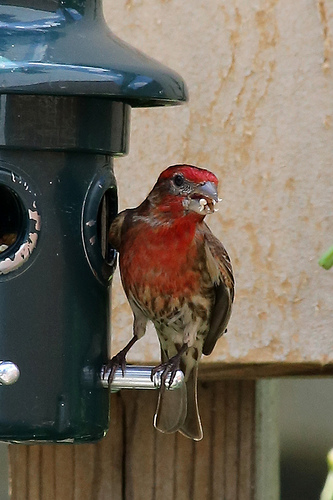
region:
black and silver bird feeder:
[0, 1, 186, 443]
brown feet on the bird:
[101, 336, 190, 389]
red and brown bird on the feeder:
[97, 161, 236, 441]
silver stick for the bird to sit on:
[99, 360, 184, 392]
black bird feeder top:
[0, 0, 191, 108]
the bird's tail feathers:
[152, 333, 205, 443]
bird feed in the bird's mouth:
[198, 195, 222, 216]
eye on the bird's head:
[170, 171, 186, 189]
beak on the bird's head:
[182, 180, 220, 216]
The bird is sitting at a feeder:
[29, 122, 321, 482]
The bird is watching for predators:
[52, 156, 276, 487]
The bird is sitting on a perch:
[54, 162, 327, 469]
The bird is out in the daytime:
[53, 162, 311, 481]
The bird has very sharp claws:
[52, 155, 310, 488]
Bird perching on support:
[111, 162, 240, 379]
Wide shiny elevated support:
[116, 368, 151, 390]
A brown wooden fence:
[6, 459, 249, 492]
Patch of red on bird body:
[115, 216, 216, 302]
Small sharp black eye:
[169, 174, 186, 187]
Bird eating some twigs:
[187, 191, 223, 213]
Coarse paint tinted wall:
[245, 173, 308, 300]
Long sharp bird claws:
[101, 356, 180, 390]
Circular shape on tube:
[6, 187, 30, 253]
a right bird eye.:
[170, 169, 188, 191]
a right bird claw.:
[99, 335, 140, 392]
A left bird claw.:
[146, 337, 192, 391]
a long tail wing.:
[175, 360, 203, 440]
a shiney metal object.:
[98, 356, 188, 439]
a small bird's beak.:
[185, 180, 221, 218]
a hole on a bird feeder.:
[79, 166, 123, 284]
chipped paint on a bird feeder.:
[0, 194, 41, 278]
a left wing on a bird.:
[195, 222, 238, 357]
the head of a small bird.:
[146, 153, 223, 217]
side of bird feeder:
[1, 0, 187, 442]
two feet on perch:
[102, 360, 186, 390]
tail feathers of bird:
[153, 363, 203, 440]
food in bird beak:
[191, 184, 219, 214]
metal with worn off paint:
[0, 204, 42, 273]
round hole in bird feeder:
[84, 171, 120, 283]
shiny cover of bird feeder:
[0, 1, 187, 107]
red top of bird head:
[158, 165, 217, 212]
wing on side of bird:
[202, 232, 236, 355]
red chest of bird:
[123, 216, 201, 295]